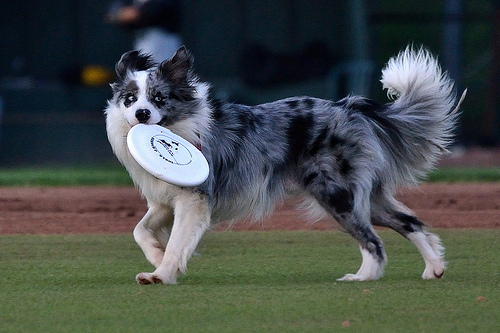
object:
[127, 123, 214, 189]
frisbee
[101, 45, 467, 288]
dog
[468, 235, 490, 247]
grass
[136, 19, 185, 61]
person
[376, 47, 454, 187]
tail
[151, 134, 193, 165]
logo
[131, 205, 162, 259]
leg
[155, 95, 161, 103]
eyes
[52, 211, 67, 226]
dirt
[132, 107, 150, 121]
nose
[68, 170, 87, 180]
part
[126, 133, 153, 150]
part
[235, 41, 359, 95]
chair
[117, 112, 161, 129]
mouth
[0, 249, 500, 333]
field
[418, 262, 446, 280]
paw